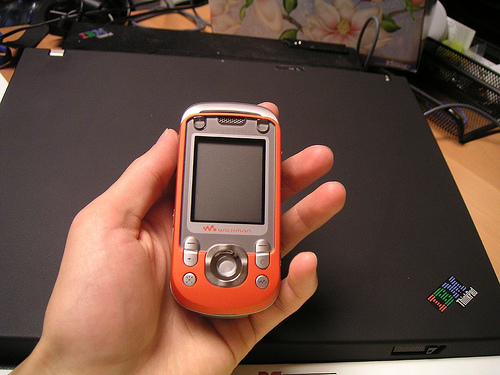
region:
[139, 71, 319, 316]
an orange cell phone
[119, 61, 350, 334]
a cell phone in a hand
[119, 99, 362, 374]
a hand holding a cell phone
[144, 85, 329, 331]
a cell phone that is off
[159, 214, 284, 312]
buttons to operate the phone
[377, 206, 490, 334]
IBM logo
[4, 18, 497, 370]
a black IBM laptop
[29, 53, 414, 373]
a hand holding an orange phone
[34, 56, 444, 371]
an orange phone with very little buttons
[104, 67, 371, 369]
a phone that fits in the hand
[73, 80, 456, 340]
A man is holding a cell phone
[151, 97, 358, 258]
the cell phone is orange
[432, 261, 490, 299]
the laptop is an IBM think pad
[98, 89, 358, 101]
the laptop is black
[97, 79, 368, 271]
the man's hand is holding a phone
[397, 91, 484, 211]
the laptop is on a table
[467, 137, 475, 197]
the table is light tan in color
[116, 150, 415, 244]
the nails are short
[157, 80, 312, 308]
the cell phone is silver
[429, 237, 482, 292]
the letters are different colors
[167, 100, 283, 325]
the hand held device is orange and silver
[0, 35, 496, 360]
a black lap top is on the table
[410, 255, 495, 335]
the laptop has a logo in the corner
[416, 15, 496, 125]
a metal storage paper holder is on the desk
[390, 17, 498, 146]
the metal storage in box is black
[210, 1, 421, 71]
a box has a flower motif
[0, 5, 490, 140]
black wires are around the table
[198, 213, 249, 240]
a logo is on the bottom of the screen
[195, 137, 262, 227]
a screen is on the device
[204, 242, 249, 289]
a silver button is on the device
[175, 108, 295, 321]
orange cell phone with screen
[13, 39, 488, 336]
black IBM think pad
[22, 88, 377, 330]
white hand holding a phone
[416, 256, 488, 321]
ibm think pad logo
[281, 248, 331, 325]
white bent pinky finger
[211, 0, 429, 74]
flower box of kleenex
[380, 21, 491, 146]
black metal organization bin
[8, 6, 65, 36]
snarl of black wires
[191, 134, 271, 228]
screen on an orange phone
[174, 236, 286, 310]
silver buttons on a phone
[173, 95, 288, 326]
cell phone with orange case and grey screen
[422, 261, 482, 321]
red,green and blue ibm logo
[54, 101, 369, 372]
hand holding a cell phone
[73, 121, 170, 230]
white thumb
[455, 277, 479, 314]
white letters on black background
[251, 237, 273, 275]
grey buttons on cell phone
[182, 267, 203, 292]
round grey button with black x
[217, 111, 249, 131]
speaker on front of cell phone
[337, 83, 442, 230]
black case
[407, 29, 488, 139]
wire rack on desk